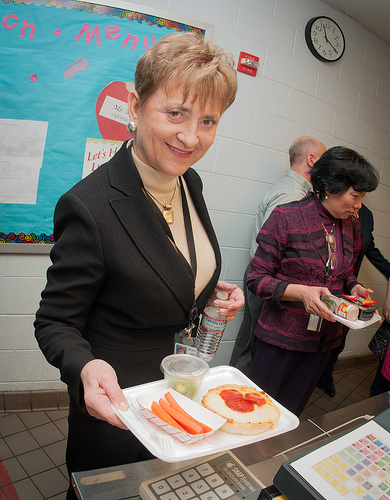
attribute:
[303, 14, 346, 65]
clock — wall clock, round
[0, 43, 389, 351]
wall — white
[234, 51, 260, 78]
fire alarm device — red, fire alarm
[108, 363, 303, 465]
tray — cafeteria tray, full, white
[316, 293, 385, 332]
their food — cafeteria tray, full, white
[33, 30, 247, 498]
woman — hungry, happy, getting her lunch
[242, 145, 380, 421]
lady — getting her lunch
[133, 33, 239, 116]
hairstyle — short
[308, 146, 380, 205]
hairstyle — short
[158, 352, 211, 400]
cup — plastic, clear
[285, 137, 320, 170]
hairstyle — short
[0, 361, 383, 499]
flooring — tile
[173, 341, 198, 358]
badge — id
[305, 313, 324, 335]
badge — id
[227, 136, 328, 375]
man — balding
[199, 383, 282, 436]
pizza — personal, pepperoni, cheese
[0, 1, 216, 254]
bulletin board — decorated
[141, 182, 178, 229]
necklace — gold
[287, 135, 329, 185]
head and ear — balding, man's